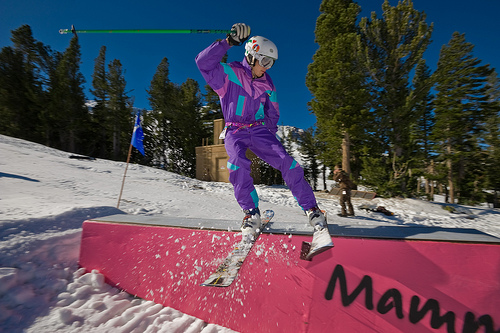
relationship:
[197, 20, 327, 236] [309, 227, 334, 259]
person wearing ski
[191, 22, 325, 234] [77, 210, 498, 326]
woman flying over ramp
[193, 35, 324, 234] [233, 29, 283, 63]
woman wears helmet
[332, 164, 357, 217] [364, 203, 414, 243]
person standing in snow